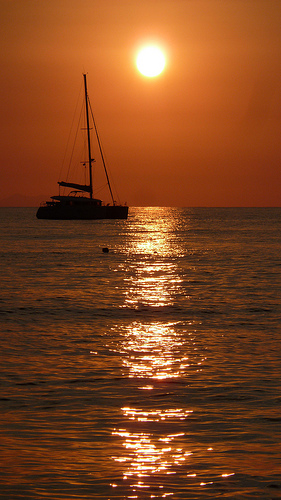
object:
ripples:
[0, 356, 281, 423]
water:
[12, 268, 275, 452]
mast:
[82, 71, 95, 199]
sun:
[132, 39, 169, 80]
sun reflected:
[96, 411, 195, 489]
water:
[158, 428, 239, 480]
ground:
[236, 71, 253, 85]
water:
[0, 207, 280, 499]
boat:
[36, 72, 129, 222]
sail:
[58, 181, 92, 191]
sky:
[2, 0, 279, 204]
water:
[25, 232, 255, 300]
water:
[164, 231, 196, 251]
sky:
[163, 59, 275, 156]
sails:
[56, 178, 89, 194]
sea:
[1, 319, 279, 497]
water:
[234, 217, 270, 279]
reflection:
[121, 211, 182, 316]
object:
[101, 245, 111, 254]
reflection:
[104, 203, 196, 498]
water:
[16, 238, 144, 265]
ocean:
[14, 220, 138, 236]